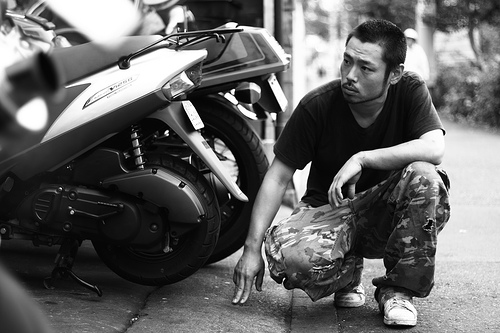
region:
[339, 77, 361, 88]
The mustache of the man kneeling next to the motorcycle.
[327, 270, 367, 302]
The man's left sneaker.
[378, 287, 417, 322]
The man's right sneaker.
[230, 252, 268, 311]
The man's left hand.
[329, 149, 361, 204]
The man's right hand.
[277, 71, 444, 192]
The t-shirt the man is wearing.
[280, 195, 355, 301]
The man's left leg.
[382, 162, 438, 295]
The man's right leg.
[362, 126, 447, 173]
The man's right arm.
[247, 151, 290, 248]
The man's left arm.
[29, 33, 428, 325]
man crouching by motorcycle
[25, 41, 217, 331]
dark motorcycle with white on rear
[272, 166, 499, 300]
man wearing camo pants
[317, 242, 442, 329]
man wearing white sneakers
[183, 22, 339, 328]
man touching pavement in photo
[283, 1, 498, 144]
trees in background in photo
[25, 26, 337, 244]
two motorcycles next to each other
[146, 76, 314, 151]
two white license plates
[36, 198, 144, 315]
motorcycle kick stand is down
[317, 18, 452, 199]
man in black t-shirt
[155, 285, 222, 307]
small white pebbles on ground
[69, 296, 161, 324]
small groove on the ground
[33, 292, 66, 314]
small oil slick on the ground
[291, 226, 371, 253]
pattern on man's pants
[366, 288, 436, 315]
laces in white sneakers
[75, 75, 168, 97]
logo on man's bike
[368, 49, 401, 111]
side whiskers on man's face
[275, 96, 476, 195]
man wearing black tee shirt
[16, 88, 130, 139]
shine on man's bike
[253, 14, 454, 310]
man crouching on the ground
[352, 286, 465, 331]
white shoes for walking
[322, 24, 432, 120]
Asian man looking at something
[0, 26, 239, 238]
motorcycle getting rest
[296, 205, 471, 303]
camouflage pants for clothing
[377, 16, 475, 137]
man in far background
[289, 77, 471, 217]
man wearing black shirt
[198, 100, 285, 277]
black motor cycle tire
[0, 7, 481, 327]
black and white photo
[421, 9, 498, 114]
trees in the background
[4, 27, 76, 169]
motorcycle exhaust pipe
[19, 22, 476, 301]
a black and white photo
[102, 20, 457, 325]
A man in a black and white photo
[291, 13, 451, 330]
A man bending down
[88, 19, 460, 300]
A man bending down behind a motorcycle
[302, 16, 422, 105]
The head of a man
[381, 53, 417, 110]
The ear of a man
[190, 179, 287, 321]
The hand of a man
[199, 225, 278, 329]
A hand touching the ground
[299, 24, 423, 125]
A man with a beard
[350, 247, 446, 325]
The foot of a man